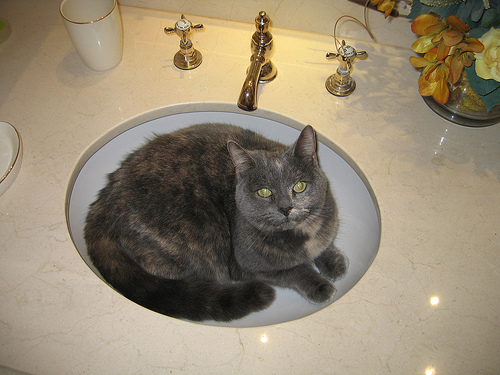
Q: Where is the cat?
A: In the sink.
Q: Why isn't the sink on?
A: The cat is in it.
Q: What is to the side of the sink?
A: A cup.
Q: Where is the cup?
A: To the side.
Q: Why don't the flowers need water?
A: They are fake.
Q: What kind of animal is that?
A: A cat.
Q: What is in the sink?
A: Cat.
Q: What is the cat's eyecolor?
A: Green.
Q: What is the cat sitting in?
A: Sink.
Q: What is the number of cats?
A: One.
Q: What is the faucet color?
A: Gold.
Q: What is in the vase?
A: Flowers.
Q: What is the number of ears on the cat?
A: Two.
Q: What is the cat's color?
A: Gray.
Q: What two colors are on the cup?
A: White and gold.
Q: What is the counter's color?
A: White.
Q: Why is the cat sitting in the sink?
A: He is comfortable there.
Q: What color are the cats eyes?
A: The cat has green eyes.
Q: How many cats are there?
A: 1 cat there.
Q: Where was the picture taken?
A: In the bathroom.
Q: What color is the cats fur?
A: The cat's fur is grey.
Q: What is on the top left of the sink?
A: A cup.